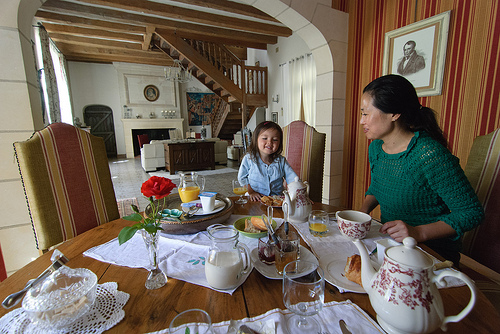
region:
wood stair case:
[131, 20, 274, 147]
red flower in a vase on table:
[122, 170, 172, 297]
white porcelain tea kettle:
[345, 225, 484, 330]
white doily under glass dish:
[4, 260, 139, 332]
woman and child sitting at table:
[223, 69, 483, 251]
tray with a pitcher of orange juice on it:
[144, 161, 224, 229]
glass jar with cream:
[192, 220, 256, 296]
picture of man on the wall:
[375, 12, 460, 110]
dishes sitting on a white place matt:
[290, 191, 477, 308]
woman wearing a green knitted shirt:
[342, 57, 489, 250]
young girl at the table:
[238, 105, 308, 209]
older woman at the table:
[344, 59, 479, 260]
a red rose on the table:
[113, 162, 193, 292]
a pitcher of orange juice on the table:
[171, 166, 213, 210]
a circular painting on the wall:
[133, 75, 172, 107]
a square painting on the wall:
[366, 5, 465, 100]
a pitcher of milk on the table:
[191, 208, 261, 293]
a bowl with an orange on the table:
[231, 206, 279, 237]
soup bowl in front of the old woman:
[326, 196, 383, 244]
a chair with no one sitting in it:
[6, 96, 141, 253]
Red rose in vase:
[115, 164, 184, 296]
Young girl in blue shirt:
[235, 111, 310, 211]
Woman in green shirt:
[347, 69, 489, 267]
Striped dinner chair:
[7, 117, 129, 257]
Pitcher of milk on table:
[192, 218, 252, 300]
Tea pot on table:
[346, 232, 484, 331]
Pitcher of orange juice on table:
[174, 164, 204, 210]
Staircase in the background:
[139, 18, 263, 153]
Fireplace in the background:
[121, 100, 191, 163]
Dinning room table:
[4, 188, 498, 330]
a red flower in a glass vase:
[107, 173, 198, 306]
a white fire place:
[119, 100, 206, 165]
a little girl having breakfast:
[231, 115, 332, 196]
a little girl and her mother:
[236, 82, 484, 247]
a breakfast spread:
[51, 152, 422, 331]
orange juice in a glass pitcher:
[170, 162, 215, 207]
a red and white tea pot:
[346, 220, 443, 332]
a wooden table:
[37, 188, 454, 330]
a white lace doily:
[7, 292, 129, 329]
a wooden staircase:
[142, 35, 279, 149]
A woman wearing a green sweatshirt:
[346, 67, 466, 252]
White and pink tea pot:
[353, 225, 464, 332]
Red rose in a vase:
[118, 170, 185, 272]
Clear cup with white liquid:
[198, 215, 261, 287]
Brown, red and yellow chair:
[16, 118, 119, 248]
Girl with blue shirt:
[234, 127, 312, 209]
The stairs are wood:
[151, 25, 270, 155]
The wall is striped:
[348, 13, 491, 155]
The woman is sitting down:
[353, 70, 490, 305]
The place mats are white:
[278, 197, 469, 287]